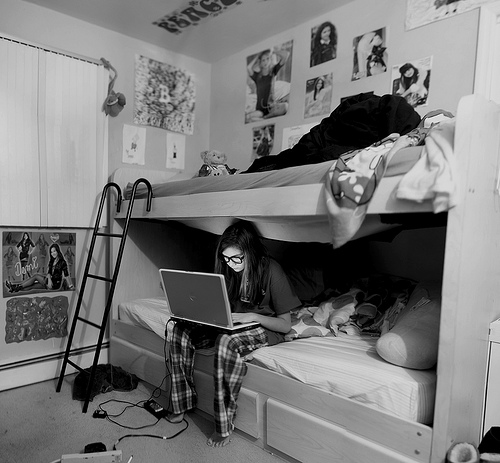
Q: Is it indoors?
A: Yes, it is indoors.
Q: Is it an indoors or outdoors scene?
A: It is indoors.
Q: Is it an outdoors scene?
A: No, it is indoors.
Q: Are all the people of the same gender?
A: Yes, all the people are female.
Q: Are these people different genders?
A: No, all the people are female.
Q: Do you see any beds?
A: Yes, there is a bed.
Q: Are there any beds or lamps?
A: Yes, there is a bed.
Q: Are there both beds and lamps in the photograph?
A: No, there is a bed but no lamps.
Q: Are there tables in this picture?
A: No, there are no tables.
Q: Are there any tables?
A: No, there are no tables.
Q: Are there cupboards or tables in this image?
A: No, there are no tables or cupboards.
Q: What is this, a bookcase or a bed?
A: This is a bed.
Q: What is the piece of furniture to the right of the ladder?
A: The piece of furniture is a bed.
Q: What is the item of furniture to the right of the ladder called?
A: The piece of furniture is a bed.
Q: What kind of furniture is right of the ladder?
A: The piece of furniture is a bed.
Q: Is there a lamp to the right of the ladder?
A: No, there is a bed to the right of the ladder.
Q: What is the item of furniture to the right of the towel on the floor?
A: The piece of furniture is a bed.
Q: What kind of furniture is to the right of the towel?
A: The piece of furniture is a bed.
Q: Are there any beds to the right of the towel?
A: Yes, there is a bed to the right of the towel.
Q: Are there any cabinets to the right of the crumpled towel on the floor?
A: No, there is a bed to the right of the towel.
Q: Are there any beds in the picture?
A: Yes, there is a bed.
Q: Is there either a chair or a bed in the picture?
A: Yes, there is a bed.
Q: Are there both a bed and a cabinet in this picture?
A: No, there is a bed but no cabinets.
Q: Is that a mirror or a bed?
A: That is a bed.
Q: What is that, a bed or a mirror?
A: That is a bed.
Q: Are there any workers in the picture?
A: No, there are no workers.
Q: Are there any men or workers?
A: No, there are no workers or men.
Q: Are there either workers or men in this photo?
A: No, there are no workers or men.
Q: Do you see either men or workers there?
A: No, there are no workers or men.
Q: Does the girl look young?
A: Yes, the girl is young.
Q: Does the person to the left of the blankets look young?
A: Yes, the girl is young.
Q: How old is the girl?
A: The girl is young.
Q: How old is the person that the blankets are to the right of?
A: The girl is young.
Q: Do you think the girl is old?
A: No, the girl is young.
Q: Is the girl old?
A: No, the girl is young.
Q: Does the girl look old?
A: No, the girl is young.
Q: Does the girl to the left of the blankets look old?
A: No, the girl is young.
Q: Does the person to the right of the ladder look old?
A: No, the girl is young.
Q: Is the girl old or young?
A: The girl is young.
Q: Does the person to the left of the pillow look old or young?
A: The girl is young.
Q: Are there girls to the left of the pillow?
A: Yes, there is a girl to the left of the pillow.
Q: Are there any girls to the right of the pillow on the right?
A: No, the girl is to the left of the pillow.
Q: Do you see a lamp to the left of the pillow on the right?
A: No, there is a girl to the left of the pillow.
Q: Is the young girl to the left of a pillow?
A: Yes, the girl is to the left of a pillow.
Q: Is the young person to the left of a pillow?
A: Yes, the girl is to the left of a pillow.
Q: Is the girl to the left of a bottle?
A: No, the girl is to the left of a pillow.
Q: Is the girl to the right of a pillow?
A: No, the girl is to the left of a pillow.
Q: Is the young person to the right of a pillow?
A: No, the girl is to the left of a pillow.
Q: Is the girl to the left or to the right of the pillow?
A: The girl is to the left of the pillow.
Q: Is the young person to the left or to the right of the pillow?
A: The girl is to the left of the pillow.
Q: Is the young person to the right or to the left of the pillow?
A: The girl is to the left of the pillow.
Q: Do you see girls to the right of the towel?
A: Yes, there is a girl to the right of the towel.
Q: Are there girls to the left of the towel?
A: No, the girl is to the right of the towel.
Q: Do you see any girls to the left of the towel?
A: No, the girl is to the right of the towel.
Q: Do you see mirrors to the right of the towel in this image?
A: No, there is a girl to the right of the towel.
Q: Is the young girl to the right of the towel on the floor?
A: Yes, the girl is to the right of the towel.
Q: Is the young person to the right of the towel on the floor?
A: Yes, the girl is to the right of the towel.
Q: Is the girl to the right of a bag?
A: No, the girl is to the right of the towel.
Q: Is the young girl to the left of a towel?
A: No, the girl is to the right of a towel.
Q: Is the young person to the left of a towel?
A: No, the girl is to the right of a towel.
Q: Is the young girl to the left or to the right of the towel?
A: The girl is to the right of the towel.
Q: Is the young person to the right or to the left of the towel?
A: The girl is to the right of the towel.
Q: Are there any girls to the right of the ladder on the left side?
A: Yes, there is a girl to the right of the ladder.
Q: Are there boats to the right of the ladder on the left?
A: No, there is a girl to the right of the ladder.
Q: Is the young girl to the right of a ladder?
A: Yes, the girl is to the right of a ladder.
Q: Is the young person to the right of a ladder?
A: Yes, the girl is to the right of a ladder.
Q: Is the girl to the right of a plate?
A: No, the girl is to the right of a ladder.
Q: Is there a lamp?
A: No, there are no lamps.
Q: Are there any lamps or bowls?
A: No, there are no lamps or bowls.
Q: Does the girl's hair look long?
A: Yes, the hair is long.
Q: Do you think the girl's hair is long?
A: Yes, the hair is long.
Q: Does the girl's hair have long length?
A: Yes, the hair is long.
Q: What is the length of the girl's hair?
A: The hair is long.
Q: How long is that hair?
A: The hair is long.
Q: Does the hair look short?
A: No, the hair is long.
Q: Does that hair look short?
A: No, the hair is long.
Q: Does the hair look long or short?
A: The hair is long.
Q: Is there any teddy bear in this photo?
A: Yes, there is a teddy bear.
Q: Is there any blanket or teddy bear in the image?
A: Yes, there is a teddy bear.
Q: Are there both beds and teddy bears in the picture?
A: Yes, there are both a teddy bear and a bed.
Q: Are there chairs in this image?
A: No, there are no chairs.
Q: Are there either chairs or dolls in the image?
A: No, there are no chairs or dolls.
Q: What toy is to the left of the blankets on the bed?
A: The toy is a teddy bear.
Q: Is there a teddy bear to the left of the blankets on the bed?
A: Yes, there is a teddy bear to the left of the blankets.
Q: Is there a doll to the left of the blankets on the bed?
A: No, there is a teddy bear to the left of the blankets.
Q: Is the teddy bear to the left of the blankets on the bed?
A: Yes, the teddy bear is to the left of the blankets.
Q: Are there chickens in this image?
A: No, there are no chickens.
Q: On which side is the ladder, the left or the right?
A: The ladder is on the left of the image.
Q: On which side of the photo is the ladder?
A: The ladder is on the left of the image.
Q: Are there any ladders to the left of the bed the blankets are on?
A: Yes, there is a ladder to the left of the bed.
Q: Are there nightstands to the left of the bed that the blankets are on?
A: No, there is a ladder to the left of the bed.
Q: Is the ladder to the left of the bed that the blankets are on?
A: Yes, the ladder is to the left of the bed.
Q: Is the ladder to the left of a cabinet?
A: No, the ladder is to the left of the bed.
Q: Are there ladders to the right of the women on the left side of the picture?
A: Yes, there is a ladder to the right of the women.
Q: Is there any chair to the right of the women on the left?
A: No, there is a ladder to the right of the women.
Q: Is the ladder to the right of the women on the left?
A: Yes, the ladder is to the right of the women.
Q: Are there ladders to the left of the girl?
A: Yes, there is a ladder to the left of the girl.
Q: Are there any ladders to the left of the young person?
A: Yes, there is a ladder to the left of the girl.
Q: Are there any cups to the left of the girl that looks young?
A: No, there is a ladder to the left of the girl.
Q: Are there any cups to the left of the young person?
A: No, there is a ladder to the left of the girl.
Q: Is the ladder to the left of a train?
A: No, the ladder is to the left of the girl.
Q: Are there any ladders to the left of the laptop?
A: Yes, there is a ladder to the left of the laptop.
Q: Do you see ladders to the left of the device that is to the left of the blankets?
A: Yes, there is a ladder to the left of the laptop.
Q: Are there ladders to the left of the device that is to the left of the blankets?
A: Yes, there is a ladder to the left of the laptop.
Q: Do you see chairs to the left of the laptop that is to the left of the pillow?
A: No, there is a ladder to the left of the laptop.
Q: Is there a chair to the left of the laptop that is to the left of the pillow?
A: No, there is a ladder to the left of the laptop.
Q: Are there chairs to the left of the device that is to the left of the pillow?
A: No, there is a ladder to the left of the laptop.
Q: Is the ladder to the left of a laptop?
A: Yes, the ladder is to the left of a laptop.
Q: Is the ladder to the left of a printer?
A: No, the ladder is to the left of a laptop.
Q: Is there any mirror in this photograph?
A: No, there are no mirrors.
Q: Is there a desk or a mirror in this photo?
A: No, there are no mirrors or desks.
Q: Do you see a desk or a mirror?
A: No, there are no mirrors or desks.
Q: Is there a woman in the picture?
A: Yes, there is a woman.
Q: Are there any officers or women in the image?
A: Yes, there is a woman.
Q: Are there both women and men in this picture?
A: No, there is a woman but no men.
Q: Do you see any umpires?
A: No, there are no umpires.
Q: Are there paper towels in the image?
A: No, there are no paper towels.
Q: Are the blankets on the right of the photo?
A: Yes, the blankets are on the right of the image.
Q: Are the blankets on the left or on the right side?
A: The blankets are on the right of the image.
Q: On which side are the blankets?
A: The blankets are on the right of the image.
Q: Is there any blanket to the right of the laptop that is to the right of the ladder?
A: Yes, there are blankets to the right of the laptop.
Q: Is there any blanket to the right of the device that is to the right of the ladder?
A: Yes, there are blankets to the right of the laptop.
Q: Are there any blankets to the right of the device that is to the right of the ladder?
A: Yes, there are blankets to the right of the laptop.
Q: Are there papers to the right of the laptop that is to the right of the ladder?
A: No, there are blankets to the right of the laptop.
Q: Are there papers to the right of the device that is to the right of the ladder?
A: No, there are blankets to the right of the laptop.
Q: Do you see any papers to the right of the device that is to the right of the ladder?
A: No, there are blankets to the right of the laptop.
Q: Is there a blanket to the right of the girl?
A: Yes, there are blankets to the right of the girl.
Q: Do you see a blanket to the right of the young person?
A: Yes, there are blankets to the right of the girl.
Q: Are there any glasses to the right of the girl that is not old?
A: No, there are blankets to the right of the girl.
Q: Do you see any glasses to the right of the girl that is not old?
A: No, there are blankets to the right of the girl.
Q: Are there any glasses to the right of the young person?
A: No, there are blankets to the right of the girl.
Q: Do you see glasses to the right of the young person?
A: No, there are blankets to the right of the girl.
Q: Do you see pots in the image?
A: No, there are no pots.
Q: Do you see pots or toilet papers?
A: No, there are no pots or toilet papers.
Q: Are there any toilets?
A: No, there are no toilets.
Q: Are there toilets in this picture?
A: No, there are no toilets.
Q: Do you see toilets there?
A: No, there are no toilets.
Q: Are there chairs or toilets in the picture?
A: No, there are no toilets or chairs.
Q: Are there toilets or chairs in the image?
A: No, there are no toilets or chairs.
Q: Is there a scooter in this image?
A: No, there are no scooters.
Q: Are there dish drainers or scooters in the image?
A: No, there are no scooters or dish drainers.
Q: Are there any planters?
A: No, there are no planters.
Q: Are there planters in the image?
A: No, there are no planters.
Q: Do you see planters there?
A: No, there are no planters.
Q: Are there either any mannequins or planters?
A: No, there are no planters or mannequins.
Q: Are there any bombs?
A: No, there are no bombs.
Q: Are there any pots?
A: No, there are no pots.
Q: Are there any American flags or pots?
A: No, there are no pots or American flags.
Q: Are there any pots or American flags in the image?
A: No, there are no pots or American flags.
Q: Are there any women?
A: Yes, there are women.